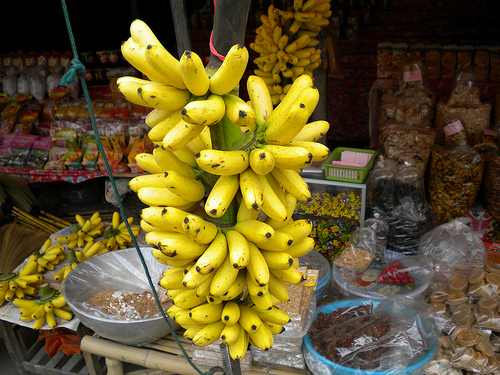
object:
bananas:
[66, 233, 79, 241]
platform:
[45, 274, 53, 280]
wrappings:
[378, 258, 442, 285]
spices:
[101, 292, 136, 313]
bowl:
[60, 246, 182, 346]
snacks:
[15, 107, 128, 165]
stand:
[33, 170, 53, 177]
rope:
[58, 4, 94, 119]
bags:
[379, 124, 437, 177]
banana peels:
[398, 136, 417, 154]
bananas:
[114, 17, 331, 360]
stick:
[211, 15, 248, 40]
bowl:
[302, 299, 438, 375]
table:
[3, 308, 11, 319]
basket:
[322, 147, 378, 183]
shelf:
[302, 173, 368, 228]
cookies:
[455, 308, 476, 325]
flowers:
[317, 191, 360, 220]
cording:
[126, 228, 152, 285]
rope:
[209, 46, 225, 61]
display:
[56, 229, 75, 254]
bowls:
[332, 250, 430, 300]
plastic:
[388, 295, 402, 311]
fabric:
[34, 171, 51, 180]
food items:
[474, 52, 489, 68]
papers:
[328, 151, 373, 180]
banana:
[180, 50, 210, 97]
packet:
[55, 106, 89, 121]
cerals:
[86, 91, 127, 120]